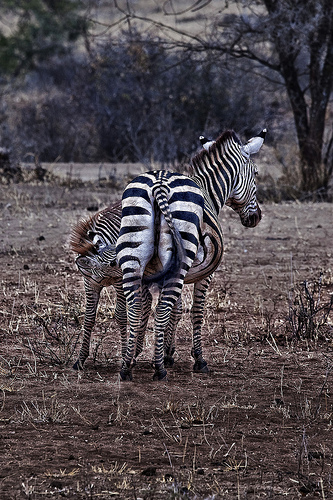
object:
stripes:
[178, 231, 200, 252]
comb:
[180, 128, 237, 175]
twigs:
[159, 402, 232, 457]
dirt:
[61, 400, 272, 482]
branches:
[108, 14, 285, 85]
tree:
[63, 0, 333, 186]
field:
[12, 72, 313, 429]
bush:
[0, 417, 333, 500]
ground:
[0, 345, 328, 500]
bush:
[280, 268, 333, 345]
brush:
[26, 275, 68, 346]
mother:
[69, 128, 264, 373]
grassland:
[6, 179, 331, 498]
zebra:
[115, 169, 203, 382]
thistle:
[284, 270, 333, 346]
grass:
[1, 326, 329, 499]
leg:
[153, 269, 191, 369]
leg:
[190, 281, 214, 361]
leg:
[114, 284, 128, 362]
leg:
[77, 289, 101, 360]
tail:
[153, 186, 187, 290]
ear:
[244, 137, 264, 154]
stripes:
[126, 176, 155, 188]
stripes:
[168, 191, 205, 212]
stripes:
[117, 226, 150, 239]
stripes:
[93, 219, 118, 239]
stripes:
[120, 276, 141, 285]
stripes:
[130, 332, 137, 338]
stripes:
[197, 148, 238, 215]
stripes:
[167, 178, 202, 189]